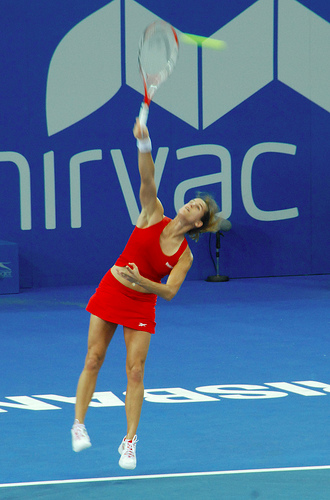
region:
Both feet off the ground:
[56, 398, 167, 487]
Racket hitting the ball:
[114, 4, 234, 157]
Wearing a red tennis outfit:
[85, 200, 196, 340]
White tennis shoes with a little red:
[65, 419, 139, 470]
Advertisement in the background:
[1, 18, 307, 256]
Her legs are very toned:
[60, 287, 155, 469]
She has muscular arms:
[124, 108, 172, 229]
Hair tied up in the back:
[188, 192, 228, 245]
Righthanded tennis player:
[66, 11, 239, 301]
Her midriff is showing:
[104, 259, 175, 300]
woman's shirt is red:
[113, 202, 198, 284]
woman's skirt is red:
[82, 276, 164, 331]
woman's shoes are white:
[59, 420, 150, 478]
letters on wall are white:
[0, 130, 322, 253]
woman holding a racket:
[119, 14, 204, 142]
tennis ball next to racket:
[178, 26, 236, 67]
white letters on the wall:
[7, 363, 298, 456]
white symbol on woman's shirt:
[158, 242, 180, 275]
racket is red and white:
[125, 22, 207, 135]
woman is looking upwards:
[169, 181, 234, 254]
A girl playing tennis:
[96, 64, 205, 413]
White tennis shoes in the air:
[54, 416, 156, 465]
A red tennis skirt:
[85, 295, 154, 344]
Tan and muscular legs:
[68, 326, 156, 426]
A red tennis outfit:
[86, 204, 185, 343]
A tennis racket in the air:
[125, 51, 174, 134]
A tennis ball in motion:
[179, 26, 234, 59]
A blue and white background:
[0, 133, 104, 242]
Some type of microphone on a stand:
[193, 209, 241, 297]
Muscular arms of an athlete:
[134, 147, 163, 215]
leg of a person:
[49, 294, 122, 452]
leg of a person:
[107, 304, 161, 470]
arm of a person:
[107, 242, 201, 306]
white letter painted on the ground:
[30, 381, 126, 415]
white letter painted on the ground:
[121, 376, 223, 406]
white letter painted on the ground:
[194, 375, 292, 405]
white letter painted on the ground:
[261, 375, 327, 401]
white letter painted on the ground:
[0, 387, 62, 420]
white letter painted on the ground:
[288, 375, 329, 391]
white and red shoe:
[113, 429, 144, 469]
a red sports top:
[115, 222, 191, 282]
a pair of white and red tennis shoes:
[70, 420, 140, 469]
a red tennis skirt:
[86, 273, 157, 334]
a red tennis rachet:
[132, 19, 183, 134]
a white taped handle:
[136, 100, 148, 135]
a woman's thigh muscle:
[122, 322, 151, 368]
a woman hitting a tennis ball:
[63, 32, 213, 469]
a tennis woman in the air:
[69, 110, 198, 491]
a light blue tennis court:
[1, 294, 329, 497]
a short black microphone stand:
[206, 225, 230, 282]